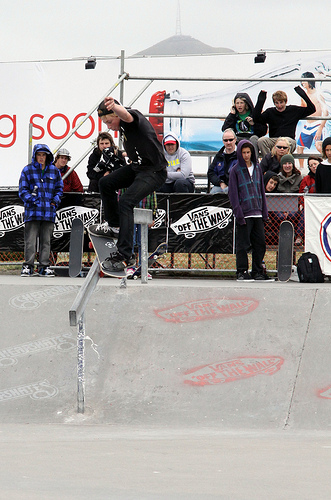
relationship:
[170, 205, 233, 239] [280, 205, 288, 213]
sign on fence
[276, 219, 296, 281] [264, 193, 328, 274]
skateboard leaning on fence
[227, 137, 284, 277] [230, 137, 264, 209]
guy with jacket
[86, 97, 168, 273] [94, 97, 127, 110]
man wearing hat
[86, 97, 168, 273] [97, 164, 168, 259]
man wearing pants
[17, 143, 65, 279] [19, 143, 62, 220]
guy wearing a plaid jacket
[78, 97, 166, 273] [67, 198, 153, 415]
man skateboarding on rail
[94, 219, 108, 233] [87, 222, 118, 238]
laces closing tennis shoe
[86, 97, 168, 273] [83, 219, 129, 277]
man on skateboard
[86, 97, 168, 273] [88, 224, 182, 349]
man doing a skateboard trick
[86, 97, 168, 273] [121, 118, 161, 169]
man wearing a shirt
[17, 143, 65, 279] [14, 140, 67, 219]
guy wearing a plaid jacket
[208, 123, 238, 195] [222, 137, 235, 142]
person wearing a sunglasses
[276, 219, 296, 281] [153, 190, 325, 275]
skateboard leaning on fence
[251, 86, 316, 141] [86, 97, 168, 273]
guy cheering man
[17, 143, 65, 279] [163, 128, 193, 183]
guy wearing a sweater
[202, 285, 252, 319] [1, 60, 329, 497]
ramp of skateboard park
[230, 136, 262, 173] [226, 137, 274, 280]
jacket on person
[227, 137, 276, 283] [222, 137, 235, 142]
guy wearing sunglasses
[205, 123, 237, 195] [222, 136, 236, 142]
person wearing sunglasses